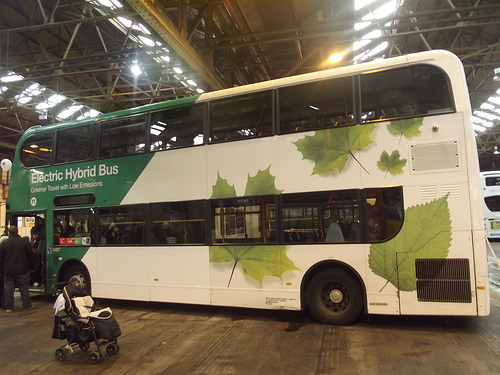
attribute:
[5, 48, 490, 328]
bus — double, white, large, green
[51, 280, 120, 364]
stroller — empty, white, black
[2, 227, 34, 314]
man — talking, waiting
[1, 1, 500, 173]
structure — exposed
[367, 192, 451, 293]
leaf — large, green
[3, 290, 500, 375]
floor — concrete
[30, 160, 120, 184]
decal — white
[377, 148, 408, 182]
leaf — small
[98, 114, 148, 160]
window — open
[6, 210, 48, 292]
door — open